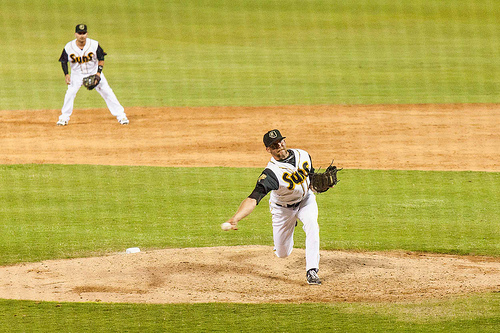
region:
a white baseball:
[219, 219, 230, 232]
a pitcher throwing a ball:
[212, 125, 346, 292]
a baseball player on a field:
[54, 21, 132, 133]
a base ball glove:
[79, 72, 103, 90]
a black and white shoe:
[304, 268, 325, 285]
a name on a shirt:
[69, 50, 96, 67]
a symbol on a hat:
[265, 129, 279, 141]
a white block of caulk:
[123, 244, 140, 258]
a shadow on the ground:
[303, 246, 390, 281]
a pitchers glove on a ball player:
[305, 160, 340, 193]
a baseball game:
[21, 17, 494, 315]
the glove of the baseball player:
[312, 165, 336, 191]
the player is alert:
[58, 25, 126, 125]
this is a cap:
[76, 23, 88, 34]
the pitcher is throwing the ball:
[221, 131, 340, 283]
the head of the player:
[264, 131, 285, 156]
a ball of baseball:
[221, 224, 229, 231]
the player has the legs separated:
[56, 84, 128, 127]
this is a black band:
[97, 63, 103, 73]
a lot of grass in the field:
[22, 179, 192, 234]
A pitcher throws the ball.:
[219, 128, 340, 285]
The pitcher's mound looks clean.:
[6, 242, 495, 306]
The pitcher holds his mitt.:
[299, 160, 339, 192]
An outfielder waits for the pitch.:
[60, 23, 127, 128]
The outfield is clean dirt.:
[170, 83, 480, 181]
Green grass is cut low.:
[206, 5, 476, 94]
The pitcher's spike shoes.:
[305, 271, 325, 283]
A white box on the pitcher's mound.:
[121, 244, 143, 254]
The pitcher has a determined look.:
[260, 128, 289, 158]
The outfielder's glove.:
[81, 73, 101, 91]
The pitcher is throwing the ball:
[218, 124, 351, 291]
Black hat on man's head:
[260, 124, 293, 165]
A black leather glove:
[305, 160, 345, 200]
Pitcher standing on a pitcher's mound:
[2, 126, 498, 310]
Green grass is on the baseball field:
[1, 1, 498, 331]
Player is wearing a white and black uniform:
[53, 21, 133, 130]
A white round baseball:
[215, 219, 236, 236]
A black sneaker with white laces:
[301, 265, 326, 289]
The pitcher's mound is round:
[2, 240, 498, 307]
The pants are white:
[58, 70, 130, 118]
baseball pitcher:
[237, 109, 347, 283]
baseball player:
[34, 12, 124, 153]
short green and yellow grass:
[245, 25, 312, 70]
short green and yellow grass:
[377, 38, 415, 59]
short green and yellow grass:
[208, 29, 270, 89]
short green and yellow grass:
[385, 193, 433, 211]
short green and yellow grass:
[111, 172, 171, 230]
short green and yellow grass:
[37, 171, 82, 209]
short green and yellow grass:
[390, 189, 460, 219]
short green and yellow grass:
[242, 16, 352, 60]